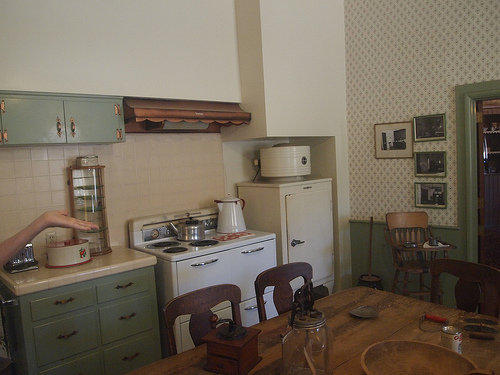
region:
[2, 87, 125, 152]
gray upper cabinets in a kitchen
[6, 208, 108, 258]
white hand presenting a kitchen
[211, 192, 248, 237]
white and red coffee percolator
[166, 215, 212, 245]
metal teapot on the stove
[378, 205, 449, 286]
old fashioned wooden highchair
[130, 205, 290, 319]
old fashioned white stove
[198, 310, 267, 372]
wooden coffee grinder on table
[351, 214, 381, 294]
wooden butter churn in the kitchen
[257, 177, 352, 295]
old fashioned ice box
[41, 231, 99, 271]
red and white cake cover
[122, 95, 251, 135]
brown oven hood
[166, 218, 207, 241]
silver tea kettle on stove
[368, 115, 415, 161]
painting on kitchen wall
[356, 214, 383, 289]
brown butter churn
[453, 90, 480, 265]
green wooden door frame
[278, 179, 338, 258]
white refrigerator door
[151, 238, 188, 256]
black burners on stove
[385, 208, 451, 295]
a brown wooden high chair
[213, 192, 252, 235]
a white tea kettle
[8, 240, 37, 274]
silver toaster sitting on counter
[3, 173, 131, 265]
Human hand welcomes to kitchen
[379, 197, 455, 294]
Wooden highchair attached tray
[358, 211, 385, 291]
Dust broom and pan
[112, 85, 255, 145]
Copper exhaust fan hood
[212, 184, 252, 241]
Old fashioned white coffee pot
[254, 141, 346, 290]
Refrigerator cooling unit top box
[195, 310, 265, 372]
Wooden crank coffee mill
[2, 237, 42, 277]
Silver bread toaster counter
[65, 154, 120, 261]
Wood glass pie pastry tower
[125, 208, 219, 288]
Silver tea kettle hot water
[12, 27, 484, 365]
An old fashion kitchen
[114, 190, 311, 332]
A white stove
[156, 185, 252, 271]
A tea pot on the stove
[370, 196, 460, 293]
A highchair in the kitchen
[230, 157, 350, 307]
An old cabinet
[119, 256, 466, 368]
The kitchen table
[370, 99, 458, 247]
Picture frames on the wall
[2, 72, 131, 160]
Cabinet is green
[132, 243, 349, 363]
The chairs are wooden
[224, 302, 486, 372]
Stuff on the table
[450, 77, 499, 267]
The door frame is green.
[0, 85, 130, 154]
The cabinets are green.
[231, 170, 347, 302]
The fridge is white.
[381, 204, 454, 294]
The chair is brown.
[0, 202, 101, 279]
Hand is sticking out.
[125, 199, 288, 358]
the oven is white.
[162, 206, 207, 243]
Tea kettle on stove.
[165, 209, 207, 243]
Tea kettle is silver.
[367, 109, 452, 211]
Pictures on the wall.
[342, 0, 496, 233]
The wall is checkered.